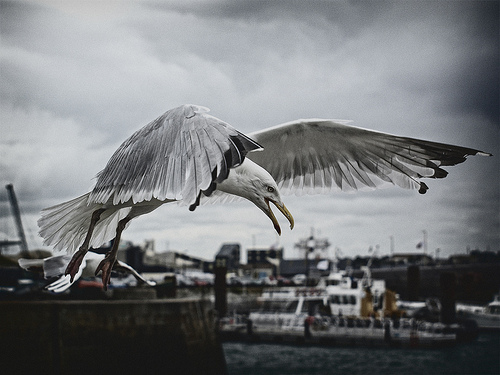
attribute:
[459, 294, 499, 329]
sail boat — in the background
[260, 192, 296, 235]
beak — yellow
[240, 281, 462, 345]
boat — white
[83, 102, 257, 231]
wing — gray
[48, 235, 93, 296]
foot — large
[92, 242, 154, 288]
foot — large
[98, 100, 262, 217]
wings — right side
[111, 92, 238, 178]
bird — white, large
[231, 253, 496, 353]
boat — in the background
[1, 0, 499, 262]
sky — very cloudy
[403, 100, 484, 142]
dark clouds — in the background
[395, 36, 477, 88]
dark clouds — in the background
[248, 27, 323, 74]
dark clouds — in the background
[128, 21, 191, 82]
dark clouds — in the background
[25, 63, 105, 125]
dark clouds — in the background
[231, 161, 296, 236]
bird's head — side view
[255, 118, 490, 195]
wing — grey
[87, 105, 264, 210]
wing — grey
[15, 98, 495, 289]
bird — grey, white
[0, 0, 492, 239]
sky — cloudy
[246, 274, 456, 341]
ships — in the background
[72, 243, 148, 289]
foot — webbed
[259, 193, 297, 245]
beak — yellow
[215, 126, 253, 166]
feather — black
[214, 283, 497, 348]
dock — boat, in the background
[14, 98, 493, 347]
bird — foot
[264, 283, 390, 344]
ship — in the background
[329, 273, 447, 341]
ship — in the background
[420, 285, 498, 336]
ship — in the background